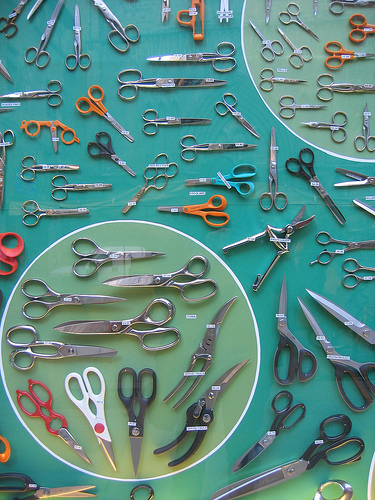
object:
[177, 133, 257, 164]
scissor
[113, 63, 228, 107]
scissor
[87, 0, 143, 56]
scissor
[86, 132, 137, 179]
scissor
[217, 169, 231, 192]
tag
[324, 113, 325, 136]
ground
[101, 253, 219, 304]
scissors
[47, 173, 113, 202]
scissors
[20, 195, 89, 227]
scissors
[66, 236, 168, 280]
scissors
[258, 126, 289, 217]
scissors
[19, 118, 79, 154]
scissors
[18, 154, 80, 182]
scissors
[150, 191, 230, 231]
closed umbrella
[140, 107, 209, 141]
scissors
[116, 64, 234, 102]
scissors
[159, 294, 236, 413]
scissors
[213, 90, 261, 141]
scissors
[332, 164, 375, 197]
silver scissors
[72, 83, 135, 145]
scissors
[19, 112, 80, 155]
scissors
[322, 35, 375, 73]
scissors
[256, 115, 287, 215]
scissors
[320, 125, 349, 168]
ground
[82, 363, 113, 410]
white handles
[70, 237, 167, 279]
scissors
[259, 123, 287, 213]
scissors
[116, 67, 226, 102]
scissors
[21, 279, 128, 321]
scissors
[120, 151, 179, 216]
double scissors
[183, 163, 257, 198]
blue scissors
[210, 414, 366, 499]
large scissors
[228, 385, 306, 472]
small scissors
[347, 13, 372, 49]
scissors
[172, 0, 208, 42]
scissors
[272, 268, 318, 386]
scissors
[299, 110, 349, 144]
scissors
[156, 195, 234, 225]
scissors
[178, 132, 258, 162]
scissors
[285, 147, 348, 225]
scissors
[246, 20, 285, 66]
scissors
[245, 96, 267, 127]
green surface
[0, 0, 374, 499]
mat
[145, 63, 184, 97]
wall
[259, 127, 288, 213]
sizzors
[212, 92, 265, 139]
sizzors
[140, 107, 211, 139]
sizzors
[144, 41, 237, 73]
sizzors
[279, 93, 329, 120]
sizzors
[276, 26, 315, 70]
scissors.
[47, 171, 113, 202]
sizzors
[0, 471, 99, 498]
scissors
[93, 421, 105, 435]
circle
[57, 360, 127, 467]
scissors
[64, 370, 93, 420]
handle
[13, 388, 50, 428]
handle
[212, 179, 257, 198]
handle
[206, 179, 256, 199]
handles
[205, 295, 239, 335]
blade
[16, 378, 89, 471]
scissors